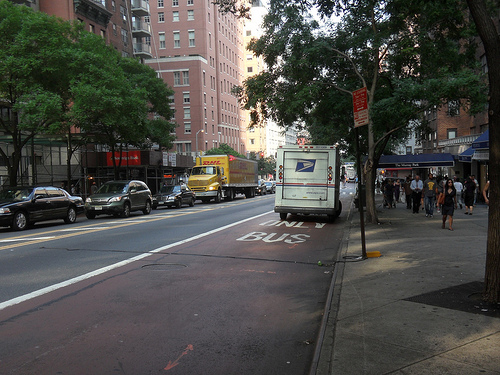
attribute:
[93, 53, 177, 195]
tree — large, green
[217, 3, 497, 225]
tree — green, large